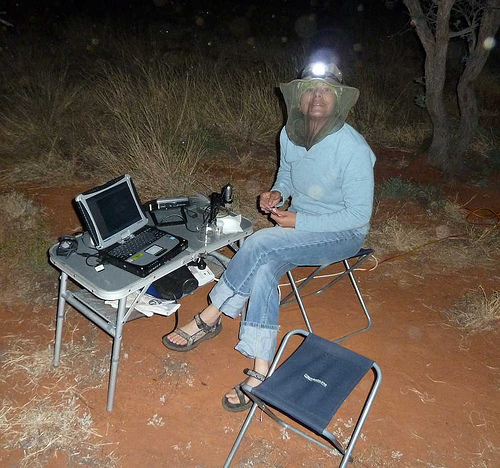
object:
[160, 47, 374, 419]
woman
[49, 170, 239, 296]
equipment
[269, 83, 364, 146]
netting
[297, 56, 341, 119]
head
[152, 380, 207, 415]
sandals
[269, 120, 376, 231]
shirt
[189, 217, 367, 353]
jeans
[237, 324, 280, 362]
cuffs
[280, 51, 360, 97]
hat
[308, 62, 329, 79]
light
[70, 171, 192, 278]
laptop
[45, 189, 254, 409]
table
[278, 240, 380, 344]
chair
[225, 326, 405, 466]
chair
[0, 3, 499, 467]
outside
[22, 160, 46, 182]
grass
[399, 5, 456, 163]
tree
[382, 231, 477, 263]
power cord